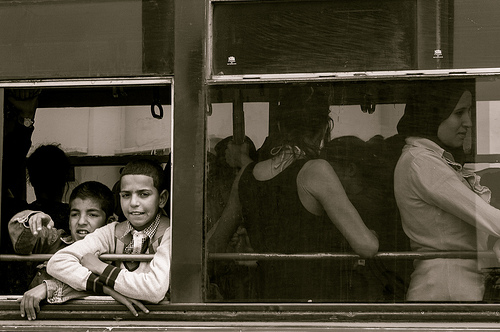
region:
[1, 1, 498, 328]
passenger bus filled with people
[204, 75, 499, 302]
closed glass window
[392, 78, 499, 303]
young lady with a black head covering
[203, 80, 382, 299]
a young lady wearing a black tank top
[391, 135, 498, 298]
fluffy white blouse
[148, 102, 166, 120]
nylon strap hand hold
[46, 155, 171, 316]
young boy wearing a white jacket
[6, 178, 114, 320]
a young man pointing at something on the street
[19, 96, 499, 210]
building behind the bus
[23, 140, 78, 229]
person in silhouette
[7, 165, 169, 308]
two young boys standing in the window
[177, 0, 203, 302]
metal window frame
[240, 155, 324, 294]
person is wearing a black tank top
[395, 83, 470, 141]
dark head dress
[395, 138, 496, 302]
long sleeve collared shirt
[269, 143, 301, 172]
tie on the woman's neck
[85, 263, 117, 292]
stripes on the boy's cuff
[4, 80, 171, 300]
window is open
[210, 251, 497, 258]
metal hand rail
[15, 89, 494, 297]
group of people standing together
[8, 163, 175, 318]
two kids looking out of a window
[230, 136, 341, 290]
black tank top on a woman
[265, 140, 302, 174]
tie around a woman's neck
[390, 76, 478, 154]
head scarf on a woman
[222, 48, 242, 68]
logo on a window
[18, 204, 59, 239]
hand pointing out the window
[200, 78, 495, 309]
closed window on a building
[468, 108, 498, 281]
reflection on a window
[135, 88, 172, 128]
pul on a curtain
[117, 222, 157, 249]
collar on a boys shirt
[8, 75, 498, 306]
people in the bus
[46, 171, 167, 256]
childrens watching outside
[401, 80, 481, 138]
a woman using scarf on her head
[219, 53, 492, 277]
window of the bus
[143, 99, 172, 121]
handle on the bus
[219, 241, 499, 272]
metal steel in the bus window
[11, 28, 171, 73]
side class of the window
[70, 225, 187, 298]
a boy wearing full hand shirt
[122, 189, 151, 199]
eyes of the boy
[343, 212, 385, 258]
elbow of the woman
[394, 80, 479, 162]
A woman is wearing a black scarf.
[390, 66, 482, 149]
A woman's head is draped in a black scarf.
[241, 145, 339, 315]
A woman is wearing a black dress.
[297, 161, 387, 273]
A woman's elbow is resting on a rail.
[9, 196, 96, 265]
A kid is point out a window.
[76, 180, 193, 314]
A kid is wearing a white sweater.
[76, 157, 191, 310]
A boy is looking out the window.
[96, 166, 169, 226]
A boy is biting is lower lip.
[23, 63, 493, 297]
People are riding in a rail car.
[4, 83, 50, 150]
A man is holding onto a rail.